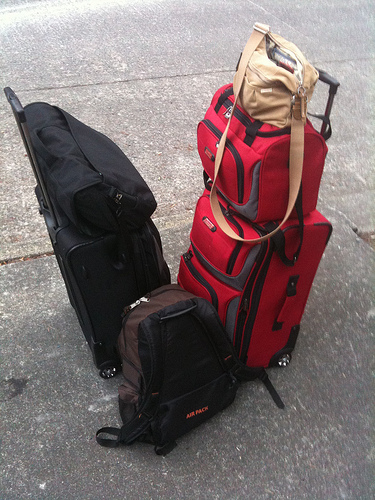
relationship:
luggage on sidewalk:
[1, 39, 348, 465] [275, 427, 333, 471]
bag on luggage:
[209, 20, 320, 244] [197, 99, 319, 389]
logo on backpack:
[182, 400, 217, 422] [103, 299, 238, 434]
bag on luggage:
[45, 111, 145, 216] [3, 85, 171, 379]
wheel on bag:
[278, 355, 305, 375] [196, 81, 329, 222]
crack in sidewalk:
[139, 57, 184, 90] [101, 45, 178, 87]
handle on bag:
[284, 295, 301, 334] [245, 226, 320, 379]